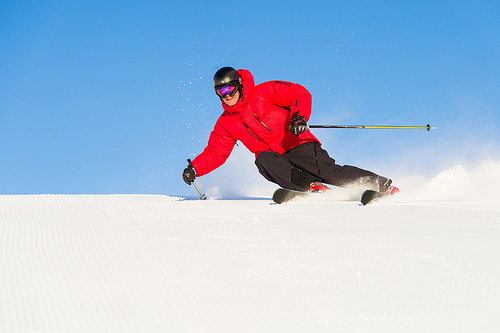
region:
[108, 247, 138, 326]
a line on white ice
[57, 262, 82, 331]
a line on white ice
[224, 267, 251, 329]
a line on white ice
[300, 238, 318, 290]
a line on white ice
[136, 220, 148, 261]
a line on white ice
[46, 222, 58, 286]
a line on white ice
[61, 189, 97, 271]
a line on white ice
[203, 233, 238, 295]
a line on white ice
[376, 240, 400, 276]
a line on white ice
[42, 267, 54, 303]
a line on white ice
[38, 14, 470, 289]
skiing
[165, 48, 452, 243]
a person is skiing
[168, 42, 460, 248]
the skier is moving quickly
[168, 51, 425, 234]
the skier leans to the side to stear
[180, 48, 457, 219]
the skier is wearing red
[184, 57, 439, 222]
the person is wearing a red sweatshirt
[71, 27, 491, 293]
it is a sunny day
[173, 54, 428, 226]
the skier has black pants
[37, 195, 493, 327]
the snow is white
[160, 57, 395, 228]
the skier is wearing goggles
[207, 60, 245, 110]
the head of a person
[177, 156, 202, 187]
a black glove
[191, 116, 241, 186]
the arm of a person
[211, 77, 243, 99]
a pair of goggles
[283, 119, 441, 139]
a black and yellow ski pole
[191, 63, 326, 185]
a red coat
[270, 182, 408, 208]
a black pair of skis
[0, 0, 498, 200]
a clear blue sky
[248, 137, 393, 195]
a pair of black pants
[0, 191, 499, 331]
white snow on the ground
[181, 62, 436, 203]
A man skiing on snow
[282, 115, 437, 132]
A ski pole held by a man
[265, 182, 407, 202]
Skis on a man's feet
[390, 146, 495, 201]
Powdered snow behind a skier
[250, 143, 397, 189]
Black men's ski pants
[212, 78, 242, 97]
Purple ski goggles covering a man's eyes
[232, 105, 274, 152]
Drawstrings on a red hoodie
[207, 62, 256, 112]
A man's face with ski goggles, helmet, and hood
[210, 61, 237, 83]
Skiing helmet on man's head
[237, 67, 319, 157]
Man wearing red hoodie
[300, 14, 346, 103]
part of the sky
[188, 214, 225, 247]
part of a snow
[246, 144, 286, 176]
part of a knee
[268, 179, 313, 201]
part of a board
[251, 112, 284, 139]
part of a zip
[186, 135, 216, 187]
part of a jacket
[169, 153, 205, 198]
part of a glove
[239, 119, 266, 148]
part of a zip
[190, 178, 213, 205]
part of a hooker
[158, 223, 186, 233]
part of a snow